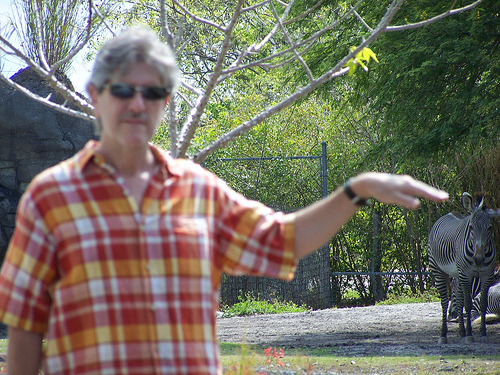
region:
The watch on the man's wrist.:
[339, 181, 369, 211]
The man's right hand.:
[339, 152, 441, 214]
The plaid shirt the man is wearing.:
[19, 140, 307, 366]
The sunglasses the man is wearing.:
[94, 79, 179, 104]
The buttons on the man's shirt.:
[134, 187, 175, 372]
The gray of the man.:
[80, 26, 186, 104]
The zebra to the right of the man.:
[424, 177, 497, 347]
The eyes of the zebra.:
[466, 216, 499, 234]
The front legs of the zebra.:
[460, 272, 495, 351]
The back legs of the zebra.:
[432, 267, 467, 343]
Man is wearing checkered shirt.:
[1, 21, 301, 373]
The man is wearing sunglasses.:
[32, 18, 196, 205]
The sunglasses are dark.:
[85, 66, 178, 114]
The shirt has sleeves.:
[3, 137, 316, 374]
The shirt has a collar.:
[0, 131, 300, 373]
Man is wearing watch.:
[13, 18, 448, 262]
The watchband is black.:
[329, 161, 376, 229]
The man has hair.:
[55, 12, 194, 169]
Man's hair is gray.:
[63, 14, 193, 166]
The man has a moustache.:
[73, 22, 178, 157]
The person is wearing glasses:
[93, 72, 188, 112]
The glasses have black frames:
[96, 76, 216, 133]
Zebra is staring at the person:
[386, 150, 498, 352]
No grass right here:
[298, 314, 413, 346]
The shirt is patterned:
[14, 122, 269, 361]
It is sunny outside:
[14, 14, 282, 166]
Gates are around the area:
[194, 127, 419, 324]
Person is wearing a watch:
[333, 175, 378, 230]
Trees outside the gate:
[268, 9, 443, 189]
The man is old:
[44, 4, 211, 198]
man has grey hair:
[91, 15, 218, 133]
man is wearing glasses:
[98, 80, 181, 127]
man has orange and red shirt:
[52, 169, 249, 365]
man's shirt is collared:
[16, 148, 223, 365]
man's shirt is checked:
[39, 134, 275, 372]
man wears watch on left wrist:
[283, 119, 448, 247]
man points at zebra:
[339, 165, 493, 287]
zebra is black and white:
[415, 176, 498, 301]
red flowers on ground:
[263, 343, 286, 373]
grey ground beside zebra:
[233, 293, 416, 357]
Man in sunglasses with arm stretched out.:
[4, 20, 439, 372]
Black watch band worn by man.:
[337, 173, 369, 211]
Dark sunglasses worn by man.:
[102, 77, 171, 103]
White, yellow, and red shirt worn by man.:
[0, 142, 295, 373]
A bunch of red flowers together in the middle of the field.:
[262, 341, 294, 366]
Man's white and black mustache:
[117, 107, 151, 125]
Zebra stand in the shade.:
[425, 192, 497, 344]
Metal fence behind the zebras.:
[210, 135, 445, 310]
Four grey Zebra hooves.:
[436, 332, 491, 344]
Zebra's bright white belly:
[439, 259, 461, 278]